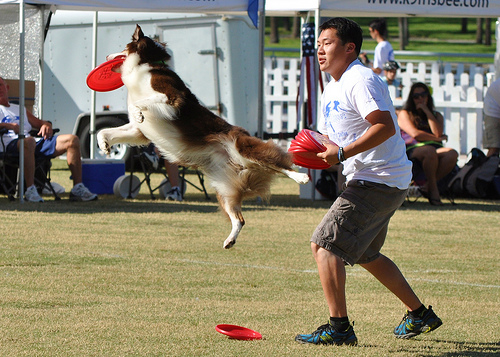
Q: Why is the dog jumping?
A: To catch the frisbee.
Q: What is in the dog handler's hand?
A: Several frisbees.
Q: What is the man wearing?
A: A shirt.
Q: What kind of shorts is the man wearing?
A: Brown ones.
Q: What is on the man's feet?
A: Shoes.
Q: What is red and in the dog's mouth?
A: A Frisbee.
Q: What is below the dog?
A: Grass.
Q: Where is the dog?
A: In the air.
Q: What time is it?
A: Afternoon.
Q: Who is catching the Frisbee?
A: Dog.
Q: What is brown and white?
A: The dog.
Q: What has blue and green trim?
A: The man's sneakers.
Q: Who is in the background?
A: The seated woman.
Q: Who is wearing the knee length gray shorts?
A: The man.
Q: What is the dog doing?
A: Jumping over a frisbee.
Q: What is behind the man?
A: A white picket fence.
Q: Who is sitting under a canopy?
A: A woman.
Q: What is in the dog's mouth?
A: A red frisbee.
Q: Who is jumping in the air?
A: A dog.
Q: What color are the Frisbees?
A: Red.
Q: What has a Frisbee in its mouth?
A: The dog.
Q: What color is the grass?
A: Green.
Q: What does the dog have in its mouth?
A: A Frisbee.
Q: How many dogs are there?
A: One.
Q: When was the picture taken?
A: Daytime.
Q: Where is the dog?
A: In the air.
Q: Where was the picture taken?
A: At a dog show.